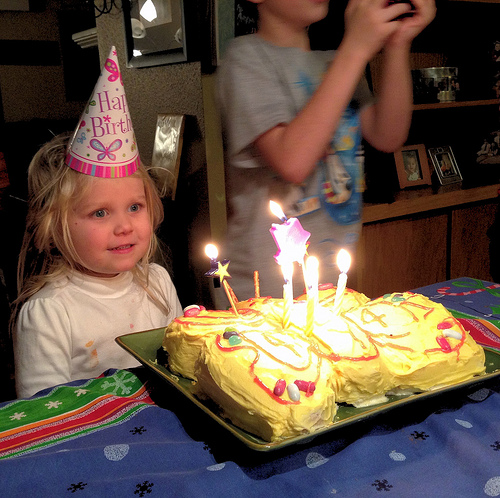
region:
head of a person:
[39, 122, 189, 283]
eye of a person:
[79, 196, 122, 223]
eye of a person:
[120, 194, 161, 215]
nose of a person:
[108, 212, 147, 238]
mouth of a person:
[94, 230, 154, 274]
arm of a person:
[295, 33, 397, 141]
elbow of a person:
[272, 145, 339, 199]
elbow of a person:
[375, 119, 422, 169]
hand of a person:
[353, 1, 401, 41]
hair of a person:
[40, 167, 70, 224]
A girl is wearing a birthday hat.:
[60, 42, 147, 182]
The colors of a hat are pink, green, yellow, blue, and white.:
[58, 39, 150, 185]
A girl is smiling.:
[17, 132, 171, 283]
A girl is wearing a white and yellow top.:
[7, 250, 191, 402]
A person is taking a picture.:
[202, 0, 444, 317]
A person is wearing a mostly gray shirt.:
[200, 26, 368, 308]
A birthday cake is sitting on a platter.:
[158, 252, 485, 452]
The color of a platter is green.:
[110, 289, 497, 456]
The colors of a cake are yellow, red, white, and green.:
[162, 285, 487, 446]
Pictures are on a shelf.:
[376, 137, 472, 197]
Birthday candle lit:
[202, 243, 244, 315]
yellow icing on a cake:
[164, 288, 486, 442]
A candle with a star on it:
[204, 240, 241, 315]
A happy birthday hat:
[61, 42, 142, 178]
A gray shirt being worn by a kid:
[219, 30, 376, 300]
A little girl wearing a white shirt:
[12, 134, 190, 401]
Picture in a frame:
[390, 143, 432, 190]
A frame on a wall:
[149, 112, 184, 199]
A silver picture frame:
[417, 65, 462, 102]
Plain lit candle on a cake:
[329, 241, 351, 323]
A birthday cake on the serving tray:
[168, 281, 493, 437]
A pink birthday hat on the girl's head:
[62, 44, 149, 182]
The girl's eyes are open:
[85, 197, 150, 229]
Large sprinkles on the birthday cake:
[272, 371, 317, 401]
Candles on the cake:
[187, 196, 372, 333]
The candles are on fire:
[275, 249, 362, 282]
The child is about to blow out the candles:
[21, 81, 179, 403]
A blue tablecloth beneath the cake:
[117, 424, 226, 496]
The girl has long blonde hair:
[26, 132, 184, 316]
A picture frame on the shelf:
[397, 142, 436, 187]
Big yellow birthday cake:
[171, 278, 488, 437]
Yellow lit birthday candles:
[266, 263, 368, 330]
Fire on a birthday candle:
[332, 249, 364, 274]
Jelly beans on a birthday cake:
[266, 369, 319, 402]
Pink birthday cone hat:
[56, 44, 151, 178]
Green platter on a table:
[96, 321, 495, 462]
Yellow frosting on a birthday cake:
[182, 345, 274, 413]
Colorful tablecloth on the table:
[0, 418, 226, 495]